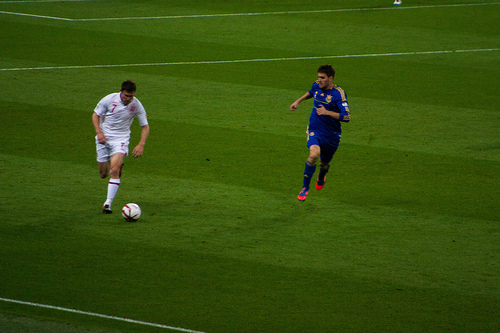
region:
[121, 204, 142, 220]
soccer ball with red stripes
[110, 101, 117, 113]
the number 7 in red text on white jersey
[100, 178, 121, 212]
white sock with red stripe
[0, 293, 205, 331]
portion of the boundary of the soccer field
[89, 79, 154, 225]
man in white uniform kicking soccer ball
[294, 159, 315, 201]
blue socks and red cleats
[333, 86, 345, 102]
gold double-stripe pattern on blue uniform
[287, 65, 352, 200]
man on opposing team seeking to intercept ball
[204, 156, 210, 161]
black patch of dirt on soccer field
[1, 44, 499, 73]
northern boundary of soccer field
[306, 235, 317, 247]
part of a field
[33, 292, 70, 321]
part of a line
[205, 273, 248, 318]
part of a ground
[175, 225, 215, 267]
part of a ground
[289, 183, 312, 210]
part of a sshie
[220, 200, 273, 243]
part of a grass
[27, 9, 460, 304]
two people playing soccer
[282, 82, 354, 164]
man wearing blue uniform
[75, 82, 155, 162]
man wearing white uniform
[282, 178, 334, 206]
man wearing red shoes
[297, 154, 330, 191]
man wearing blue socks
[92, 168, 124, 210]
man wearing white socks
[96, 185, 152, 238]
white and red soccer ball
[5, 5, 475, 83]
white lines on field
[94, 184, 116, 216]
man wearing white shoes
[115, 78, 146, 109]
man with brown hair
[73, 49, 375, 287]
Two men in the field playing soccer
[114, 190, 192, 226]
Soccer ball on the ground.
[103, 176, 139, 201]
The soccer player is wearing white socks.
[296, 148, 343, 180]
The player is wearing blue socks.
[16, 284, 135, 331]
A white line in the field.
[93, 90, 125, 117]
The number 7 on man shirt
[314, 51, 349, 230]
The man wearing blue is running.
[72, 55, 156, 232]
The man wearing white is kicking the ball.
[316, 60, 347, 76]
The man has short hair.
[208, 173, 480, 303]
The field is green.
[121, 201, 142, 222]
red and white soccer ball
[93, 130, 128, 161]
white and red shorts man is wearing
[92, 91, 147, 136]
man wearing a white and red top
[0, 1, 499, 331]
yellow lines on the field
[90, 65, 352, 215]
two men playing soccer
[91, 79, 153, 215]
man is kicking the ball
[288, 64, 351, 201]
man running towards the ball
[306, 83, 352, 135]
blue and gold top man is wearing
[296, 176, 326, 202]
red and blue tennis shoes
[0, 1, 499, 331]
green grass men are playing on